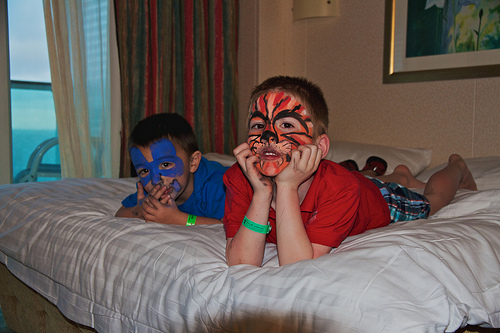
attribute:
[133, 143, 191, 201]
face paint — blue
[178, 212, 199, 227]
wrist band — green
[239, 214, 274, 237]
wrist band — green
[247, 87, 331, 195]
boy — black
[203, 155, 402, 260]
shirt — red 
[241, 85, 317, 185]
face — orange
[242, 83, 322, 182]
face — red